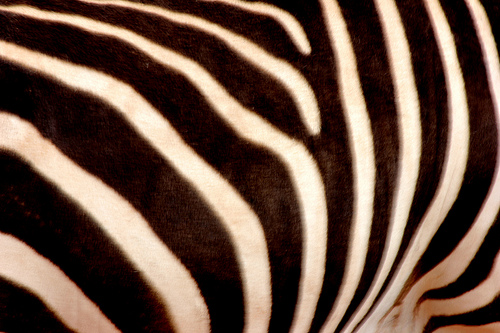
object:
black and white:
[1, 2, 499, 333]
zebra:
[0, 0, 500, 333]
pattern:
[1, 2, 499, 333]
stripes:
[415, 0, 500, 330]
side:
[4, 4, 499, 333]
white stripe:
[315, 1, 380, 332]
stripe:
[220, 0, 312, 57]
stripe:
[6, 234, 126, 329]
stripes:
[0, 12, 303, 333]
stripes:
[308, 135, 355, 333]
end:
[294, 32, 315, 59]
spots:
[4, 186, 62, 236]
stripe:
[352, 0, 450, 333]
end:
[396, 250, 456, 290]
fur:
[1, 0, 500, 332]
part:
[411, 183, 499, 331]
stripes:
[0, 0, 304, 139]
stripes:
[360, 287, 436, 332]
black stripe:
[337, 1, 403, 333]